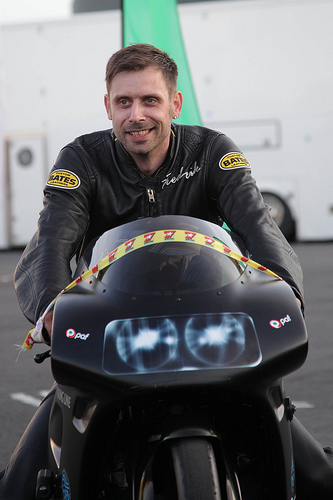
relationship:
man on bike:
[45, 53, 269, 250] [0, 184, 333, 500]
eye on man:
[137, 80, 169, 117] [48, 56, 296, 306]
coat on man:
[41, 133, 296, 282] [11, 40, 307, 349]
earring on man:
[166, 109, 185, 128] [88, 65, 232, 176]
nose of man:
[120, 104, 150, 127] [81, 36, 209, 174]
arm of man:
[5, 185, 84, 307] [86, 40, 201, 187]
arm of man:
[218, 169, 275, 275] [93, 49, 192, 174]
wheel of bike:
[152, 419, 235, 495] [0, 184, 333, 500]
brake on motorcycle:
[26, 349, 53, 369] [25, 214, 311, 498]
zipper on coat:
[142, 188, 158, 206] [12, 122, 306, 327]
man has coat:
[11, 40, 307, 349] [12, 122, 306, 327]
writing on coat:
[158, 161, 205, 192] [12, 122, 306, 327]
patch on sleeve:
[44, 165, 82, 192] [6, 143, 90, 331]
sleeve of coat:
[6, 143, 90, 331] [12, 122, 306, 327]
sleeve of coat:
[206, 131, 310, 315] [12, 122, 306, 327]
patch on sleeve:
[213, 150, 253, 172] [206, 131, 310, 315]